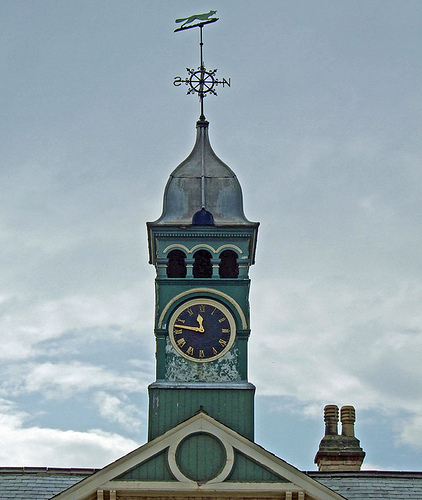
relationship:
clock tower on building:
[143, 112, 265, 432] [5, 402, 420, 495]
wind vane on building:
[168, 4, 235, 122] [0, 113, 420, 498]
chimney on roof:
[314, 404, 367, 472] [307, 471, 420, 498]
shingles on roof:
[2, 474, 54, 490] [2, 462, 100, 498]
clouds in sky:
[11, 296, 138, 429] [17, 299, 127, 424]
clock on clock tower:
[167, 297, 237, 364] [145, 114, 261, 442]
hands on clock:
[171, 311, 210, 335] [167, 297, 237, 364]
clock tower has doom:
[145, 114, 261, 442] [151, 109, 253, 224]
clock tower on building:
[145, 114, 261, 442] [0, 113, 420, 498]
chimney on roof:
[309, 396, 370, 471] [283, 468, 421, 498]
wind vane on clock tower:
[168, 4, 235, 122] [145, 114, 261, 442]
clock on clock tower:
[163, 294, 239, 364] [145, 114, 261, 442]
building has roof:
[0, 113, 420, 498] [0, 460, 420, 493]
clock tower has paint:
[145, 114, 261, 442] [157, 360, 244, 379]